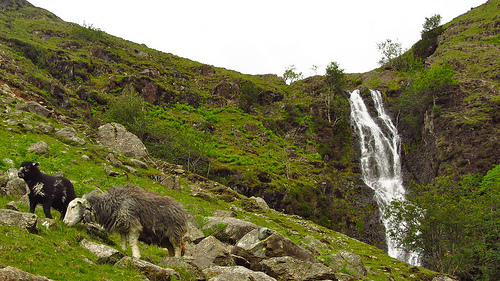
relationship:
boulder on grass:
[86, 112, 156, 172] [9, 3, 480, 263]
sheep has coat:
[56, 180, 198, 266] [86, 185, 190, 243]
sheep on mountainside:
[56, 180, 198, 266] [13, 131, 263, 280]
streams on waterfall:
[346, 85, 405, 159] [342, 78, 428, 275]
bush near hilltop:
[372, 30, 412, 76] [406, 3, 498, 70]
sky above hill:
[93, 5, 414, 45] [4, 1, 499, 157]